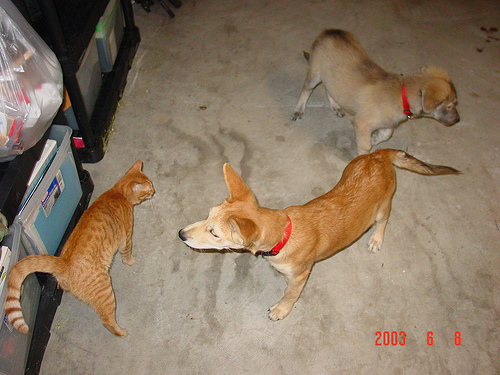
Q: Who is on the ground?
A: Dogs and cat.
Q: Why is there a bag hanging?
A: For garbage.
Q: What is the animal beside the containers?
A: Cat.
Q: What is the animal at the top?
A: Puppy.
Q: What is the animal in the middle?
A: Dog.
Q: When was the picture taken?
A: Night time.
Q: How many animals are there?
A: Three.